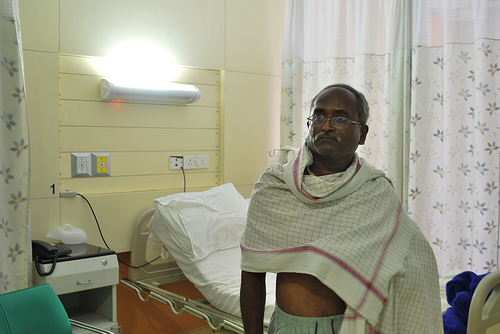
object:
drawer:
[31, 253, 121, 296]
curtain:
[276, 6, 499, 288]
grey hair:
[308, 82, 372, 126]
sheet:
[237, 146, 445, 334]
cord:
[72, 166, 187, 269]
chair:
[0, 281, 74, 334]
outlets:
[170, 156, 184, 170]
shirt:
[442, 269, 495, 332]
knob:
[76, 280, 93, 285]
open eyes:
[313, 113, 325, 122]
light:
[89, 39, 203, 104]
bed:
[117, 181, 453, 334]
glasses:
[305, 113, 366, 130]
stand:
[33, 240, 124, 334]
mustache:
[313, 130, 346, 159]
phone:
[31, 238, 75, 278]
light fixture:
[98, 75, 203, 104]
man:
[236, 79, 444, 334]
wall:
[17, 0, 284, 255]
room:
[0, 0, 500, 334]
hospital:
[1, 0, 500, 334]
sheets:
[180, 207, 210, 220]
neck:
[302, 151, 356, 175]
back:
[0, 280, 76, 334]